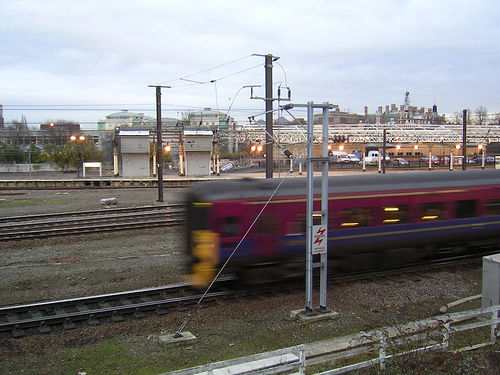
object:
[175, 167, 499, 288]
train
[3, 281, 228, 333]
track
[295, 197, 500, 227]
windows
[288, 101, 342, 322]
pole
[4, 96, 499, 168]
power lines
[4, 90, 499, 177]
buildings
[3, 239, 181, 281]
gravel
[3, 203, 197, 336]
tracks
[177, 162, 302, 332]
line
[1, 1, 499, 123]
sky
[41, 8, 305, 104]
clouds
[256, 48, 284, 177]
electrical pole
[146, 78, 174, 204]
electrical pole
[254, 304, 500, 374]
fence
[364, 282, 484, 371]
bush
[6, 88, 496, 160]
buildings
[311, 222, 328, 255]
sign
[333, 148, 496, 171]
vehicles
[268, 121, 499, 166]
building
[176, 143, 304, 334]
stabilizing wire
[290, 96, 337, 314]
utility pole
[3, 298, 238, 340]
railroad ties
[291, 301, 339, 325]
footer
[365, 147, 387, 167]
vehicle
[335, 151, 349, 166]
vehicle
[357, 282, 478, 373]
shrub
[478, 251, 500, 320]
box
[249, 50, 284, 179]
utility pole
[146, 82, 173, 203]
utility pole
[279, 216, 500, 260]
stripe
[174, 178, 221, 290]
front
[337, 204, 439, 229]
lights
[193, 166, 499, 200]
top